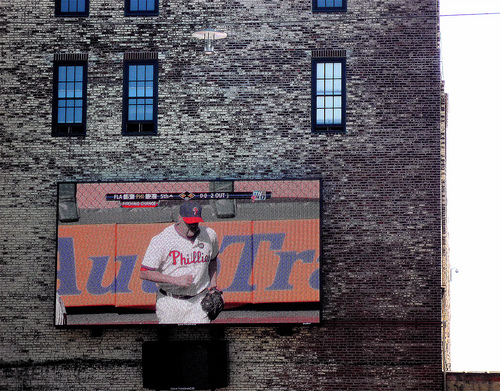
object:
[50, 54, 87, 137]
window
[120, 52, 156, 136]
window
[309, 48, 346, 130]
window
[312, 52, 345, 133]
frame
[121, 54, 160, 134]
frame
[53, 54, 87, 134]
frame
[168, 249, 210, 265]
letters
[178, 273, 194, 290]
hand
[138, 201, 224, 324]
baseball player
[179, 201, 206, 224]
cap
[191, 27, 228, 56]
light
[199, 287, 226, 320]
glove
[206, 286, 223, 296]
hand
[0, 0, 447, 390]
brick wall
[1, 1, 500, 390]
building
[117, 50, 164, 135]
window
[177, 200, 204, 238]
head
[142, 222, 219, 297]
shirt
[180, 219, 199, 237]
face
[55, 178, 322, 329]
screen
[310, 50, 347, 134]
black framed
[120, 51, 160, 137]
black framed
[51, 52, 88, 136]
black framed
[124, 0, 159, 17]
black framed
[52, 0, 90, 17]
black framed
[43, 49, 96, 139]
window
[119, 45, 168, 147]
window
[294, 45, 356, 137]
window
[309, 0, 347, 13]
window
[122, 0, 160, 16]
window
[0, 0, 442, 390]
wall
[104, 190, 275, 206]
scoreboard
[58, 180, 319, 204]
top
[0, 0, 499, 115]
sky